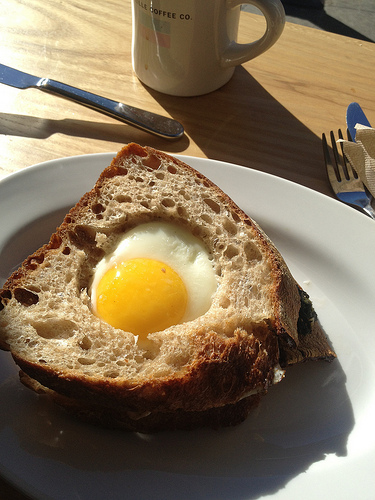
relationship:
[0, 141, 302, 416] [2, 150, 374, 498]
bread on plate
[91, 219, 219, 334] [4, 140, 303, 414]
egg inside bread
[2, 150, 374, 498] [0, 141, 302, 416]
plate beneath bread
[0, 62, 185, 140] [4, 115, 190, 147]
knife casting shadow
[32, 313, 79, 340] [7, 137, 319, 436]
hole inside bread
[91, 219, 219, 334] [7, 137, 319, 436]
egg inside bread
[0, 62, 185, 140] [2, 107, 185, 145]
knife casting shadow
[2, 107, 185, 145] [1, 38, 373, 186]
shadow on table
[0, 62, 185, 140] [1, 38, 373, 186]
knife on table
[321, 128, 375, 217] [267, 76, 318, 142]
fork on a table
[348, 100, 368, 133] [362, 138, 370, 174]
knife wrapped in a napkin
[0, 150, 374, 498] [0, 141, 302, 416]
plate contains bread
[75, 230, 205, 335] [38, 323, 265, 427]
egg cooked into bread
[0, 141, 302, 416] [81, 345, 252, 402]
bread crust brown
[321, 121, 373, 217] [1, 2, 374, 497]
fork on table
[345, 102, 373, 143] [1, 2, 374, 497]
knife on table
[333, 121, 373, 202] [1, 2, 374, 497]
napkin on table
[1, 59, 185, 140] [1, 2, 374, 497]
knife on table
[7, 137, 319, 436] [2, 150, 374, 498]
bread on plate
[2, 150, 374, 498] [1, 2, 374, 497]
plate on table